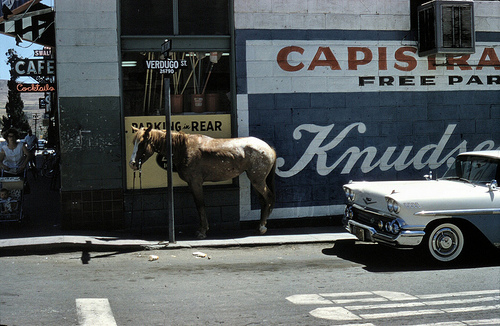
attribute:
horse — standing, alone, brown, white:
[118, 99, 301, 231]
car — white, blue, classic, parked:
[344, 139, 497, 265]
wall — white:
[251, 8, 484, 219]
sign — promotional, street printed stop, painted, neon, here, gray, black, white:
[142, 55, 191, 72]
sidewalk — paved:
[35, 222, 75, 248]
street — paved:
[99, 265, 301, 317]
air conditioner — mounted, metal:
[412, 8, 486, 65]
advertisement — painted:
[223, 38, 473, 231]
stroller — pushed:
[0, 166, 27, 234]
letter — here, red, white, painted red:
[259, 111, 492, 183]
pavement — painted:
[306, 276, 422, 325]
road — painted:
[144, 277, 219, 323]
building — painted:
[54, 6, 493, 178]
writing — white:
[300, 101, 369, 185]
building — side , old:
[5, 7, 484, 213]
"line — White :
[64, 284, 115, 324]